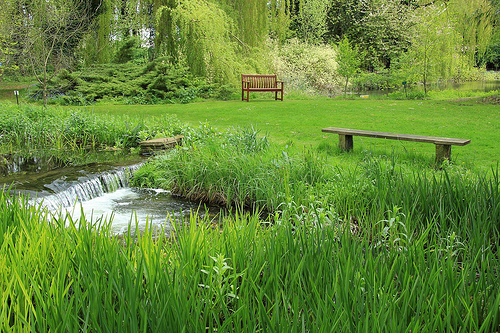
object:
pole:
[12, 96, 39, 110]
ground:
[43, 92, 62, 109]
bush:
[286, 55, 330, 88]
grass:
[276, 204, 454, 319]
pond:
[56, 156, 196, 228]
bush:
[345, 4, 466, 100]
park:
[13, 18, 453, 310]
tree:
[42, 9, 86, 98]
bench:
[233, 70, 284, 102]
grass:
[235, 98, 273, 118]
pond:
[49, 161, 179, 223]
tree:
[45, 22, 101, 107]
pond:
[63, 170, 208, 243]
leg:
[245, 92, 255, 105]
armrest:
[238, 77, 252, 91]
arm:
[241, 75, 253, 87]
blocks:
[425, 145, 453, 171]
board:
[316, 117, 474, 141]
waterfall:
[74, 178, 114, 199]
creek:
[41, 155, 158, 225]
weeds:
[314, 147, 465, 307]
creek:
[115, 122, 218, 236]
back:
[240, 78, 278, 90]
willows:
[175, 11, 224, 79]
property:
[101, 19, 471, 328]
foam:
[85, 198, 115, 226]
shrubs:
[26, 61, 207, 111]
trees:
[7, 1, 345, 90]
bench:
[298, 105, 478, 203]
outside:
[2, 202, 478, 324]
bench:
[299, 105, 474, 185]